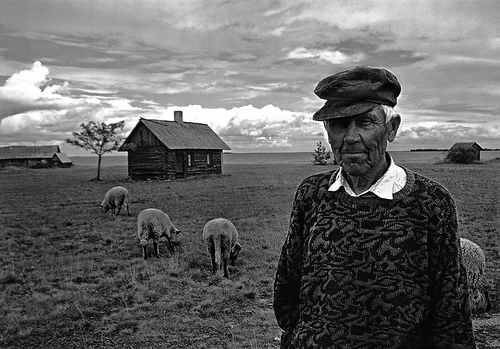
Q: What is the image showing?
A: It is showing a field.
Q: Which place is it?
A: It is a field.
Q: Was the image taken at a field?
A: Yes, it was taken in a field.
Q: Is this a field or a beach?
A: It is a field.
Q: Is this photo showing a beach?
A: No, the picture is showing a field.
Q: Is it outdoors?
A: Yes, it is outdoors.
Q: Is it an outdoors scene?
A: Yes, it is outdoors.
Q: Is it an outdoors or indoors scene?
A: It is outdoors.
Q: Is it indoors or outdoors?
A: It is outdoors.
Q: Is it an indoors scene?
A: No, it is outdoors.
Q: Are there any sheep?
A: Yes, there is a sheep.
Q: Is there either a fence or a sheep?
A: Yes, there is a sheep.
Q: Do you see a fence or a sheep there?
A: Yes, there is a sheep.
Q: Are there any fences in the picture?
A: No, there are no fences.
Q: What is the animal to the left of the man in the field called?
A: The animal is a sheep.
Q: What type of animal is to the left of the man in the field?
A: The animal is a sheep.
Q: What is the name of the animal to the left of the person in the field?
A: The animal is a sheep.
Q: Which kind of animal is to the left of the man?
A: The animal is a sheep.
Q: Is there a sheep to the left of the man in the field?
A: Yes, there is a sheep to the left of the man.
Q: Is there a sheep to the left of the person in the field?
A: Yes, there is a sheep to the left of the man.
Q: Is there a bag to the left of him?
A: No, there is a sheep to the left of the man.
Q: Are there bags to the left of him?
A: No, there is a sheep to the left of the man.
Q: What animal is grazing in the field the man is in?
A: The animal is a sheep.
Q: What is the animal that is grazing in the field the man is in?
A: The animal is a sheep.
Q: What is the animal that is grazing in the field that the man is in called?
A: The animal is a sheep.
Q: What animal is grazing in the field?
A: The animal is a sheep.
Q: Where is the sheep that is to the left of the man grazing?
A: The sheep is grazing in the field.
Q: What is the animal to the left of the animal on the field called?
A: The animal is a sheep.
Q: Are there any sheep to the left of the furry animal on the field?
A: Yes, there is a sheep to the left of the animal.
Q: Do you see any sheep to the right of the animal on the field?
A: No, the sheep is to the left of the animal.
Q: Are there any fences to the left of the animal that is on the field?
A: No, there is a sheep to the left of the animal.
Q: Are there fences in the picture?
A: No, there are no fences.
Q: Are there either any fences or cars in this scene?
A: No, there are no fences or cars.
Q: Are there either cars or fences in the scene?
A: No, there are no fences or cars.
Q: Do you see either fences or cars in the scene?
A: No, there are no fences or cars.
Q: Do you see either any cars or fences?
A: No, there are no fences or cars.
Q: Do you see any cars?
A: No, there are no cars.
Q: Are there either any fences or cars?
A: No, there are no cars or fences.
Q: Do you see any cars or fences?
A: No, there are no cars or fences.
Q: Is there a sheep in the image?
A: Yes, there is a sheep.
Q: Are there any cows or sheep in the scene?
A: Yes, there is a sheep.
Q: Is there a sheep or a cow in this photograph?
A: Yes, there is a sheep.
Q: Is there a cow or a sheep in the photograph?
A: Yes, there is a sheep.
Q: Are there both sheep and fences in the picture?
A: No, there is a sheep but no fences.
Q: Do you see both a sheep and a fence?
A: No, there is a sheep but no fences.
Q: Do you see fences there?
A: No, there are no fences.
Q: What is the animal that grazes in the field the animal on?
A: The animal is a sheep.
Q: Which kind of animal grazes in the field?
A: The animal is a sheep.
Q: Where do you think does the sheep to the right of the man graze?
A: The sheep grazes in the field.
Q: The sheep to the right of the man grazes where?
A: The sheep grazes in the field.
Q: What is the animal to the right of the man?
A: The animal is a sheep.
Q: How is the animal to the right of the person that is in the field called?
A: The animal is a sheep.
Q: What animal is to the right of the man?
A: The animal is a sheep.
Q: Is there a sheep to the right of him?
A: Yes, there is a sheep to the right of the man.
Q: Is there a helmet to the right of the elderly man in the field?
A: No, there is a sheep to the right of the man.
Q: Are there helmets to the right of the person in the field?
A: No, there is a sheep to the right of the man.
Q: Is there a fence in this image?
A: No, there are no fences.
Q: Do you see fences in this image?
A: No, there are no fences.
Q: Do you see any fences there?
A: No, there are no fences.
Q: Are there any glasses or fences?
A: No, there are no fences or glasses.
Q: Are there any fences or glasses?
A: No, there are no fences or glasses.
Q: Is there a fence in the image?
A: No, there are no fences.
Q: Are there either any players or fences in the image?
A: No, there are no fences or players.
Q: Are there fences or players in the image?
A: No, there are no fences or players.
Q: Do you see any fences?
A: No, there are no fences.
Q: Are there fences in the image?
A: No, there are no fences.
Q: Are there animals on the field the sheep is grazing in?
A: Yes, there is an animal on the field.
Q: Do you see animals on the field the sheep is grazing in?
A: Yes, there is an animal on the field.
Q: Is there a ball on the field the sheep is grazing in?
A: No, there is an animal on the field.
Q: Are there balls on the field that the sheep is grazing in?
A: No, there is an animal on the field.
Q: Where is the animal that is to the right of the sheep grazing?
A: The animal is grazing in the field.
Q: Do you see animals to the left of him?
A: Yes, there is an animal to the left of the man.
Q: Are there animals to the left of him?
A: Yes, there is an animal to the left of the man.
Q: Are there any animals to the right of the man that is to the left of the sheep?
A: No, the animal is to the left of the man.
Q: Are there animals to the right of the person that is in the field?
A: No, the animal is to the left of the man.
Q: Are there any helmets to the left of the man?
A: No, there is an animal to the left of the man.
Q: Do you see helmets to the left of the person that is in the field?
A: No, there is an animal to the left of the man.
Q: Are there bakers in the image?
A: No, there are no bakers.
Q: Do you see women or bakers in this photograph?
A: No, there are no bakers or women.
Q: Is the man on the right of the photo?
A: Yes, the man is on the right of the image.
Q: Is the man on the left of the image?
A: No, the man is on the right of the image.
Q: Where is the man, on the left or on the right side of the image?
A: The man is on the right of the image.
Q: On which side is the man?
A: The man is on the right of the image.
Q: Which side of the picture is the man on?
A: The man is on the right of the image.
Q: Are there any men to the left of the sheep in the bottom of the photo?
A: Yes, there is a man to the left of the sheep.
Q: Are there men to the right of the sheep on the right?
A: No, the man is to the left of the sheep.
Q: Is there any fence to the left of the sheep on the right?
A: No, there is a man to the left of the sheep.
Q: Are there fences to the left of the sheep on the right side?
A: No, there is a man to the left of the sheep.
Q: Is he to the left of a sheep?
A: Yes, the man is to the left of a sheep.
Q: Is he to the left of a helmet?
A: No, the man is to the left of a sheep.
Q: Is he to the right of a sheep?
A: No, the man is to the left of a sheep.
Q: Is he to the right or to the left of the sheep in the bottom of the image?
A: The man is to the left of the sheep.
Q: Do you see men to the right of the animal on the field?
A: Yes, there is a man to the right of the animal.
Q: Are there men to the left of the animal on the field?
A: No, the man is to the right of the animal.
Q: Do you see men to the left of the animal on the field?
A: No, the man is to the right of the animal.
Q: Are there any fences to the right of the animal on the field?
A: No, there is a man to the right of the animal.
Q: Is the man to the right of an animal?
A: Yes, the man is to the right of an animal.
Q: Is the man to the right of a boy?
A: No, the man is to the right of an animal.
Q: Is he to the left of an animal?
A: No, the man is to the right of an animal.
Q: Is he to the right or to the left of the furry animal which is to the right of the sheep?
A: The man is to the right of the animal.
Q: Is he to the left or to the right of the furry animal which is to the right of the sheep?
A: The man is to the right of the animal.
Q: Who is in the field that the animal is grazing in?
A: The man is in the field.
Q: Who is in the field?
A: The man is in the field.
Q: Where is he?
A: The man is in the field.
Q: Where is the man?
A: The man is in the field.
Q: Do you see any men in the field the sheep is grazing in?
A: Yes, there is a man in the field.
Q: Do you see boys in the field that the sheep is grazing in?
A: No, there is a man in the field.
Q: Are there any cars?
A: No, there are no cars.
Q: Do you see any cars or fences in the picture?
A: No, there are no cars or fences.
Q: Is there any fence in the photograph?
A: No, there are no fences.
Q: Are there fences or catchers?
A: No, there are no fences or catchers.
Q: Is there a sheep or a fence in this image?
A: Yes, there is a sheep.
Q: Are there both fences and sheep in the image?
A: No, there is a sheep but no fences.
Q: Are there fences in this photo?
A: No, there are no fences.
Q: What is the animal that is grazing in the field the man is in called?
A: The animal is a sheep.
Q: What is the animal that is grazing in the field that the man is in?
A: The animal is a sheep.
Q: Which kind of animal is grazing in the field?
A: The animal is a sheep.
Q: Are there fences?
A: No, there are no fences.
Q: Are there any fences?
A: No, there are no fences.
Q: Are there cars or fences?
A: No, there are no fences or cars.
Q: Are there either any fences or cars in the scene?
A: No, there are no fences or cars.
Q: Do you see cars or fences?
A: No, there are no fences or cars.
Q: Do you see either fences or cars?
A: No, there are no fences or cars.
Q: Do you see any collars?
A: Yes, there is a collar.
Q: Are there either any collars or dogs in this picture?
A: Yes, there is a collar.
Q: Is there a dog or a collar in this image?
A: Yes, there is a collar.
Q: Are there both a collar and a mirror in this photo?
A: No, there is a collar but no mirrors.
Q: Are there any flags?
A: No, there are no flags.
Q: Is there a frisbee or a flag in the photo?
A: No, there are no flags or frisbees.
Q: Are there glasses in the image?
A: No, there are no glasses.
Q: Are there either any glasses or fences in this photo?
A: No, there are no glasses or fences.